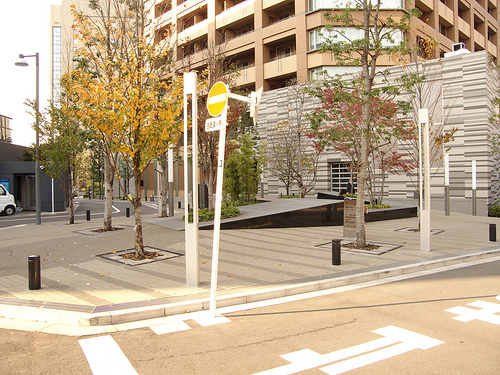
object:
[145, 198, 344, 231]
ramp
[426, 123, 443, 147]
branches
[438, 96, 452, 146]
branches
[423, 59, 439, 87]
branches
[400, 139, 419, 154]
branches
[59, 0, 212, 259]
tree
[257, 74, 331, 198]
tree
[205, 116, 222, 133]
sign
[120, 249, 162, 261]
hole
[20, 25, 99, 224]
tree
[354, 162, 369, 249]
trunk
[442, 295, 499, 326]
white line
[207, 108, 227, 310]
sign post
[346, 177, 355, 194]
man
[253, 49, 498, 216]
building lobby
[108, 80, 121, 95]
leaves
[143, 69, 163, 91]
leaves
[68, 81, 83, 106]
leaves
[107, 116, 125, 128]
leaves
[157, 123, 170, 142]
leaves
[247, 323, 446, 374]
paint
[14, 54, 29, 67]
light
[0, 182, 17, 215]
car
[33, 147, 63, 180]
leaves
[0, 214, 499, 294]
shadow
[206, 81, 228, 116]
sign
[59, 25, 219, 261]
trees sidwalk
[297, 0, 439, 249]
trees sidwalk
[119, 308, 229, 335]
line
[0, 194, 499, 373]
floor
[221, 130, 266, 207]
tree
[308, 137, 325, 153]
flower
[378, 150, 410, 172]
flower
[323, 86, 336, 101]
flower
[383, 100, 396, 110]
flower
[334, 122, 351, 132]
flower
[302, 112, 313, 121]
leaf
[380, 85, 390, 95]
leaf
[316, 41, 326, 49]
leaf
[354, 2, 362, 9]
leaf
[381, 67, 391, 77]
leaf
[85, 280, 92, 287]
leaf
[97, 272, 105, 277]
leaf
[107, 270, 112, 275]
leaf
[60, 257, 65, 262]
leaf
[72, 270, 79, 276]
leaf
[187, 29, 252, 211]
tree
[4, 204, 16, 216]
wheel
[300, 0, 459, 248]
tree